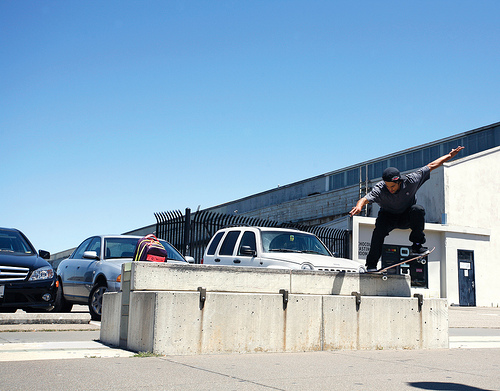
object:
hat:
[381, 165, 401, 180]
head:
[382, 167, 402, 194]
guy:
[349, 145, 464, 272]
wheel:
[379, 273, 390, 281]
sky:
[0, 1, 499, 254]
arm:
[356, 185, 381, 205]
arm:
[410, 154, 449, 183]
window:
[261, 232, 334, 257]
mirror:
[240, 246, 258, 259]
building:
[47, 122, 500, 308]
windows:
[345, 167, 359, 186]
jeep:
[201, 226, 365, 275]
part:
[133, 234, 169, 263]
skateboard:
[370, 245, 436, 280]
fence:
[152, 206, 351, 266]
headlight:
[29, 265, 53, 283]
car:
[0, 228, 61, 312]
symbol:
[405, 191, 413, 196]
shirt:
[363, 165, 431, 214]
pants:
[366, 204, 426, 269]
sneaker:
[366, 265, 377, 274]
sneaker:
[412, 245, 423, 257]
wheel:
[420, 257, 427, 266]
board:
[369, 246, 435, 274]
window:
[1, 230, 34, 254]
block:
[0, 311, 92, 324]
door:
[455, 247, 476, 305]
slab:
[130, 259, 415, 296]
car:
[57, 235, 195, 319]